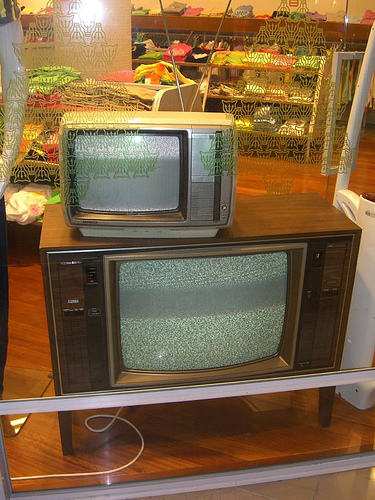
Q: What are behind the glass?
A: Televisions.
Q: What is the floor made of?
A: Wood.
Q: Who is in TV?
A: No one.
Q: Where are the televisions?
A: Behind the glass.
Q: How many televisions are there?
A: Two.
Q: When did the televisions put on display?
A: Last week.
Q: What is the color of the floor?
A: Brown.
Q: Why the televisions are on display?
A: They are vintage.